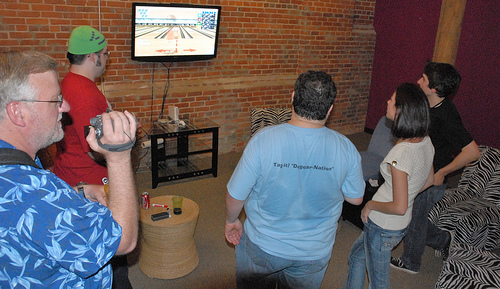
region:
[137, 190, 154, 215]
a soft drink can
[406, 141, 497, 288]
furniture with a zebra print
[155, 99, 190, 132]
a wii console on the black shelf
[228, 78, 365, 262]
a man worked up a sweat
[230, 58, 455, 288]
People playing wii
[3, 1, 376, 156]
a red brick wall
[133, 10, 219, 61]
a mounted flat screen TV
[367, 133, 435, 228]
girl wears a white cap sleeved T-shirt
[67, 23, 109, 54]
man wears a green cap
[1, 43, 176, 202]
a man using a video camera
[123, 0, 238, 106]
a tv mounted on the wall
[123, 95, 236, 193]
a black tv stand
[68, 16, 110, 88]
a man wearing a green hat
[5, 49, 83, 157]
a man with gray hair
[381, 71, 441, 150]
a woman with black hair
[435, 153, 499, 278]
a zebra print couch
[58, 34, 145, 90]
a man with glasses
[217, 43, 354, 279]
a man wearing a blue shirt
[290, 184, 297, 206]
part of a shirt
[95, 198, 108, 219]
part of a shirt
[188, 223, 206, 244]
part of a floor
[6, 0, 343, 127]
a brick wall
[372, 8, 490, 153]
a purple wall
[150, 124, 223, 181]
a black tv stand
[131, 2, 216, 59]
a television on the wall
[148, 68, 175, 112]
cords hanging from the television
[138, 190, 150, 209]
a can on the table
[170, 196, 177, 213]
a drink on the table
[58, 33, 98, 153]
a man in a red shirt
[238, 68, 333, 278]
a man in a blue shirt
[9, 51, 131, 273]
a man holding a camera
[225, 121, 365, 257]
a light blue t-shirt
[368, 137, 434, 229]
a white knit blouse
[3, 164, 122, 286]
a blue Hawaiian shirt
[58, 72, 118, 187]
a man's red t-shirt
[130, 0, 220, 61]
a wall-mounted TV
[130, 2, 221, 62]
a flat screen television set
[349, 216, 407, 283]
a pair of blue jeans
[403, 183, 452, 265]
a pair of black jeans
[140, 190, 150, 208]
a red soda can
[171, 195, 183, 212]
a year green drinking glass